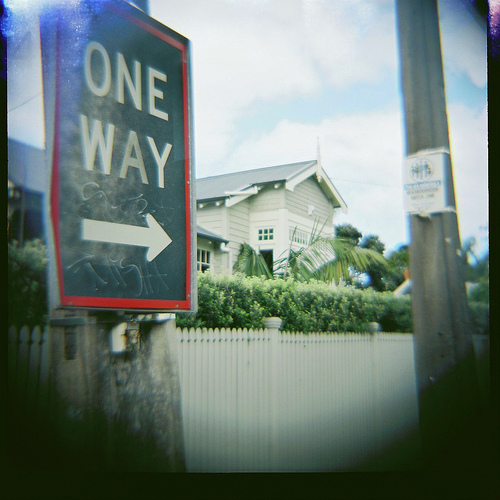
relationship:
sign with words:
[46, 1, 198, 315] [81, 41, 174, 187]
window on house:
[196, 247, 210, 272] [6, 137, 349, 276]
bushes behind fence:
[9, 247, 497, 336] [1, 325, 498, 474]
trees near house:
[338, 223, 490, 309] [6, 137, 349, 276]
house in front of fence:
[6, 137, 349, 276] [1, 325, 498, 474]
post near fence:
[41, 0, 185, 473] [1, 325, 498, 474]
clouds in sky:
[251, 104, 493, 226] [1, 1, 498, 263]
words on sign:
[81, 41, 174, 187] [46, 1, 198, 315]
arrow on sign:
[82, 213, 173, 262] [46, 1, 198, 315]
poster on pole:
[405, 152, 446, 221] [393, 2, 478, 470]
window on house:
[254, 226, 277, 239] [6, 137, 349, 276]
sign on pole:
[46, 1, 198, 315] [41, 0, 185, 473]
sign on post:
[46, 1, 198, 315] [41, 0, 185, 473]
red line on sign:
[179, 48, 190, 313] [46, 1, 198, 315]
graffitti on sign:
[63, 179, 169, 298] [46, 1, 198, 315]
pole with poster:
[393, 2, 478, 470] [405, 152, 446, 221]